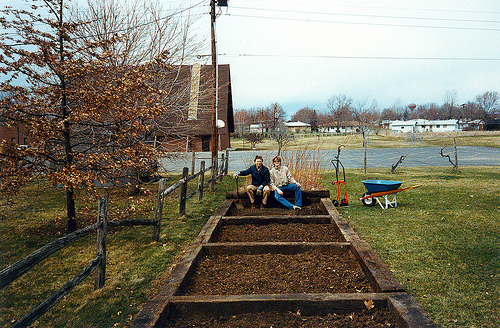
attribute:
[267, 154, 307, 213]
boy — little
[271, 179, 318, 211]
pant — blue, brown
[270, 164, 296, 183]
shirt — brown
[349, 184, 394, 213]
wheel — blue, barrow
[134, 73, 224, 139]
roof — brown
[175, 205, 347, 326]
court — tarmaced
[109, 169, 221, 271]
fence — wooden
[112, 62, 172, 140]
leave — branch, orange, small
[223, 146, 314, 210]
people — sitting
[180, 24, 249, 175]
post — wooden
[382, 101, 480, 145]
building — white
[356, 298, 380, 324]
leaf — dirt